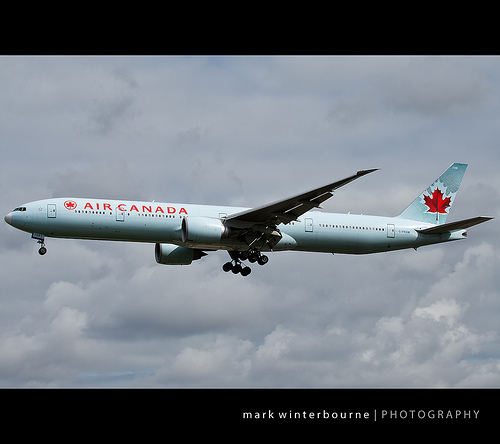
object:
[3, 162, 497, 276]
airplane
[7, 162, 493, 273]
plane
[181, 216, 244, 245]
engine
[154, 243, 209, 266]
engine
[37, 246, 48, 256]
wheel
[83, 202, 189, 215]
air canada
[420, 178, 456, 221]
logo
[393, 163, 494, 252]
tail